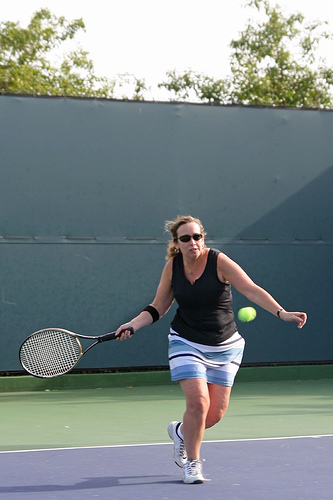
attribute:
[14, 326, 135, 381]
racket — brown, black, silver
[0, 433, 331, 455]
line — white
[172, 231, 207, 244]
glasses — dark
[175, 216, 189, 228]
hair — brown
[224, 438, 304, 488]
paint — white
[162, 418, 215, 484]
shoes — white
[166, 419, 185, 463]
shoe — grey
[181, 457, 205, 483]
shoe — grey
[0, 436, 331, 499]
court — dark, grey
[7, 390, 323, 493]
court — purple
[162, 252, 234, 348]
shirt — black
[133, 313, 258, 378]
skirt — blue, white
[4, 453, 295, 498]
paint — purple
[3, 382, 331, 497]
court — purple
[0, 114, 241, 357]
wall — green